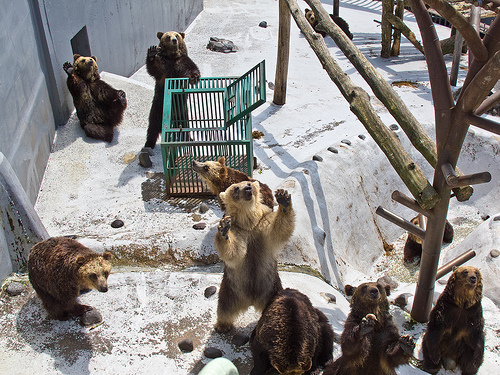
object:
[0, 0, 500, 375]
ground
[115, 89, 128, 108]
foot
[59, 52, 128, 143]
bear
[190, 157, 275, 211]
bear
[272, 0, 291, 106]
poles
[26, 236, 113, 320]
bear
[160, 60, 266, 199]
cage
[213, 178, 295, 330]
bear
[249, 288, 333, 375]
bear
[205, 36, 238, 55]
small stone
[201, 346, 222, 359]
stone on the ground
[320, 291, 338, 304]
small stone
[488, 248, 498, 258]
small stone visible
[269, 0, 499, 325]
wooden structure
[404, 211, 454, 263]
coloured bears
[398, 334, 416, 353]
black pads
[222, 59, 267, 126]
small square door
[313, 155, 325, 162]
dark round rocks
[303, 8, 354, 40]
bear almost hidden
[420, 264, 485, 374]
happy faced bear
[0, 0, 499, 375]
bear enclosure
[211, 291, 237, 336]
standing on two legs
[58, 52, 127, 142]
sitting down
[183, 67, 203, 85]
holding cage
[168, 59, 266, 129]
cage door is open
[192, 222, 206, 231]
rocks on the ground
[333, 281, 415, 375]
bears are looking up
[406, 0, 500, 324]
trees in the closure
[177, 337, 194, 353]
rocks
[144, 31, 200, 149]
bears are brown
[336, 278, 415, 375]
down and waving